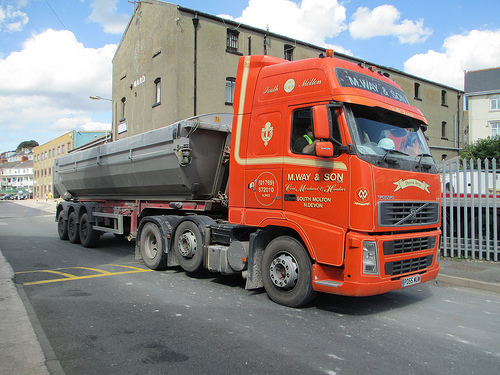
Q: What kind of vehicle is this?
A: A truck.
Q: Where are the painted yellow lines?
A: On the pavement.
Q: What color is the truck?
A: Orange.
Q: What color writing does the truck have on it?
A: Yellow.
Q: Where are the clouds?
A: In the sky.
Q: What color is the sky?
A: Blue.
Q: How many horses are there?
A: None.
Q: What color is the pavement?
A: Dark gray.